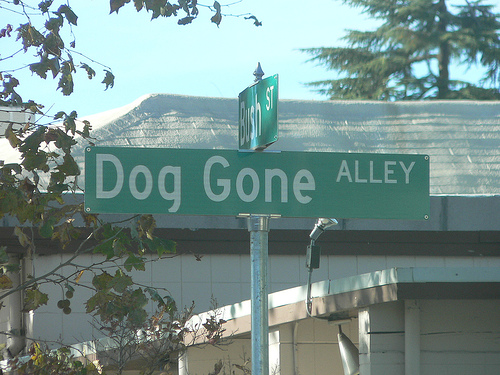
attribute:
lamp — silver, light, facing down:
[318, 317, 375, 374]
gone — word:
[193, 152, 319, 212]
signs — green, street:
[52, 47, 472, 360]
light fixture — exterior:
[333, 324, 365, 374]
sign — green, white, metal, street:
[90, 146, 419, 215]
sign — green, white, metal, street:
[227, 77, 287, 137]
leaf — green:
[140, 233, 180, 259]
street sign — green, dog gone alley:
[75, 120, 432, 237]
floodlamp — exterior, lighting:
[274, 189, 366, 264]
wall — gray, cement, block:
[0, 258, 492, 350]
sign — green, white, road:
[73, 121, 454, 233]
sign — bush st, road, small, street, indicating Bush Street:
[238, 73, 279, 150]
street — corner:
[33, 84, 485, 374]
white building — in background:
[2, 91, 499, 371]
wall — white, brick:
[155, 254, 339, 311]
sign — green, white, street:
[77, 143, 437, 231]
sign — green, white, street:
[223, 70, 290, 147]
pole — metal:
[240, 212, 271, 372]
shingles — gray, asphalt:
[116, 102, 228, 139]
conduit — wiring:
[306, 240, 323, 280]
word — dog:
[90, 153, 180, 215]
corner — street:
[46, 62, 450, 371]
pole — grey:
[241, 212, 287, 372]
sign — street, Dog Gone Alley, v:
[85, 135, 443, 226]